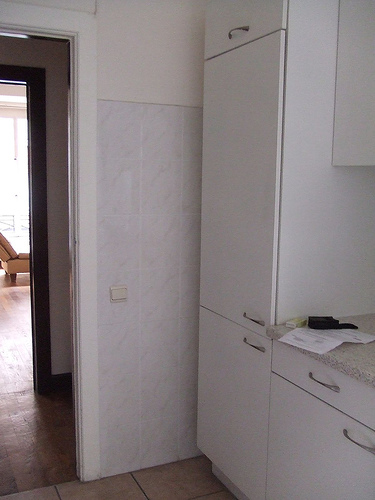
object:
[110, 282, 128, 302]
switch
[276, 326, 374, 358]
paper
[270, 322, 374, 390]
counter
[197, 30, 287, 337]
cabinet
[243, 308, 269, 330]
handle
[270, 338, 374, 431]
drawer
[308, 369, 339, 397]
handle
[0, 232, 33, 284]
couch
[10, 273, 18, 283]
leg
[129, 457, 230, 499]
tile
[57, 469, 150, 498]
tile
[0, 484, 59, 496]
tile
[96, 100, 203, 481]
wall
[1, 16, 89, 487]
doorway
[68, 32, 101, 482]
frame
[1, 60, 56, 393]
doorway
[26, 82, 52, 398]
jamb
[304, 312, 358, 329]
case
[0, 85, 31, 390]
room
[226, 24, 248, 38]
handle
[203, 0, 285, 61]
cabinet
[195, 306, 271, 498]
cabinet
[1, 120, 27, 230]
window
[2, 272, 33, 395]
flooring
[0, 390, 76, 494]
hallway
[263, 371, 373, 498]
cabinet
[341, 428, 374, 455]
handle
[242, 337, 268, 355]
handle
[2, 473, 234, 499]
floor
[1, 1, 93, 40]
frame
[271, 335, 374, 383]
edge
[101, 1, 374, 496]
kitchen